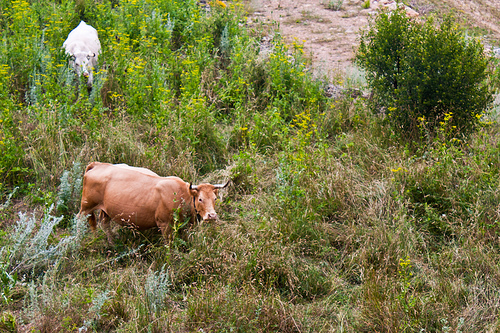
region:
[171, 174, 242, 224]
head of a cow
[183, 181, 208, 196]
ear of a cow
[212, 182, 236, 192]
ear of a cow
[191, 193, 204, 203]
eye of a cow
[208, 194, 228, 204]
eye of a cow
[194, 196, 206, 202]
an eye of a cow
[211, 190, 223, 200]
an eye of a cow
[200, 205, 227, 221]
nose of a cow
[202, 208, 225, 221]
mouth of a cow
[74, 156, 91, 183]
tail of a cow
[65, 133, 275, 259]
brown cow in the grass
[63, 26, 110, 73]
white cow in the grass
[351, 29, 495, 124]
bush on the grass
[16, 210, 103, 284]
wild green plants in grass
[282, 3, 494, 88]
bare ground in the grass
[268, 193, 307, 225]
patch of green grass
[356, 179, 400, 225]
patch of brown grass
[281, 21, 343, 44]
rocks on the ground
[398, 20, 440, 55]
yellow plants in bush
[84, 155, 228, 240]
this is a cow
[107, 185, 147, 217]
this is the belly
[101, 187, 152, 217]
the belly is fat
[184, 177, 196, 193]
this is the horn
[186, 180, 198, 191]
the horn is sharp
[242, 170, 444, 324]
these are the grass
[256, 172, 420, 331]
the grass are long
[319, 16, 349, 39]
this is the ground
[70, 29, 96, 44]
the cow is white in color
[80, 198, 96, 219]
this is the leg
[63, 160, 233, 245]
the cow has horns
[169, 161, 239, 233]
the cow has horns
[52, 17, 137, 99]
the cow is white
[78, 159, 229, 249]
a large steer on side of mountain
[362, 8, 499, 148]
A small green bush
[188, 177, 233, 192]
horns on a brown steer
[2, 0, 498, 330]
a steer in the wild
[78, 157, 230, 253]
brown cow in tall grass